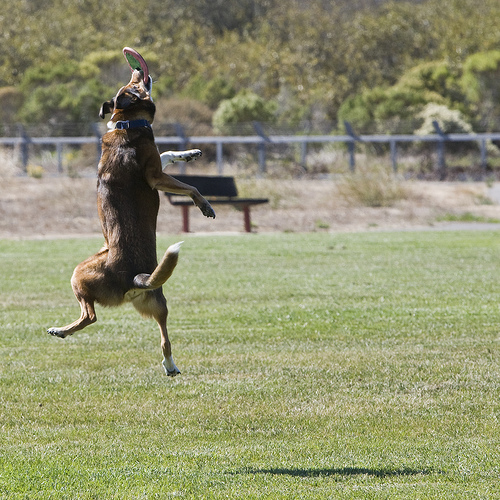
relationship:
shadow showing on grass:
[222, 466, 453, 480] [0, 231, 499, 500]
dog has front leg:
[47, 68, 217, 379] [160, 150, 201, 163]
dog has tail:
[47, 68, 217, 379] [135, 242, 181, 294]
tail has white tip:
[135, 242, 181, 294] [168, 240, 182, 257]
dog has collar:
[47, 68, 217, 379] [107, 119, 154, 129]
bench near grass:
[165, 175, 270, 234] [0, 231, 499, 500]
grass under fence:
[3, 172, 499, 230] [1, 128, 498, 192]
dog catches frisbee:
[47, 68, 217, 379] [124, 47, 152, 82]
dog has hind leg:
[47, 68, 217, 379] [47, 254, 123, 338]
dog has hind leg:
[47, 68, 217, 379] [130, 293, 181, 376]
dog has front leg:
[47, 68, 217, 379] [142, 150, 216, 219]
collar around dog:
[107, 119, 154, 129] [47, 68, 217, 379]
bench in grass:
[165, 175, 270, 234] [0, 231, 499, 500]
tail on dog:
[135, 242, 181, 294] [47, 68, 217, 379]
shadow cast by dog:
[222, 466, 453, 480] [47, 68, 217, 379]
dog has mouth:
[47, 68, 217, 379] [134, 70, 153, 90]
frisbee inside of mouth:
[124, 47, 152, 82] [134, 70, 153, 90]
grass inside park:
[0, 231, 499, 500] [2, 1, 499, 500]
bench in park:
[165, 175, 270, 234] [2, 1, 499, 500]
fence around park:
[1, 128, 498, 192] [2, 1, 499, 500]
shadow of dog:
[222, 466, 453, 480] [47, 68, 217, 379]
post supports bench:
[183, 205, 190, 235] [165, 175, 270, 234]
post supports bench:
[245, 208, 252, 233] [165, 175, 270, 234]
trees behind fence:
[1, 1, 491, 133] [1, 128, 498, 192]